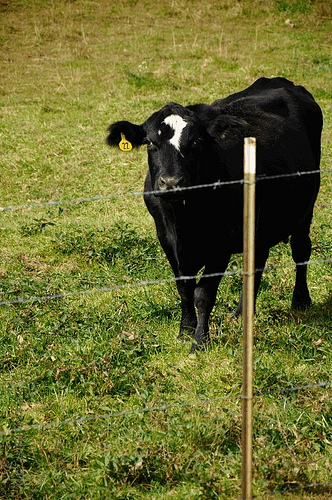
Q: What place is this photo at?
A: It is at the field.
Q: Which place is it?
A: It is a field.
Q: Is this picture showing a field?
A: Yes, it is showing a field.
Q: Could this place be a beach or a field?
A: It is a field.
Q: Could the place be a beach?
A: No, it is a field.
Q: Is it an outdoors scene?
A: Yes, it is outdoors.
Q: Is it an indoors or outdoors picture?
A: It is outdoors.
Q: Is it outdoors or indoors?
A: It is outdoors.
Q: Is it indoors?
A: No, it is outdoors.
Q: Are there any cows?
A: Yes, there is a cow.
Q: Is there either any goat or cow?
A: Yes, there is a cow.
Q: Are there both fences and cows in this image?
A: Yes, there are both a cow and a fence.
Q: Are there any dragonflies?
A: No, there are no dragonflies.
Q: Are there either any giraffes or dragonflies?
A: No, there are no dragonflies or giraffes.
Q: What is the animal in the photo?
A: The animal is a cow.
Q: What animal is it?
A: The animal is a cow.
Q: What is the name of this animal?
A: This is a cow.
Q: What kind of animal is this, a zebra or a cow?
A: This is a cow.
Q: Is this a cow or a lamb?
A: This is a cow.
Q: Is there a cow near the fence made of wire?
A: Yes, there is a cow near the fence.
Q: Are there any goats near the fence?
A: No, there is a cow near the fence.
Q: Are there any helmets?
A: No, there are no helmets.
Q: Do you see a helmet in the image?
A: No, there are no helmets.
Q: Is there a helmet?
A: No, there are no helmets.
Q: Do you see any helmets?
A: No, there are no helmets.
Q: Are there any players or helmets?
A: No, there are no helmets or players.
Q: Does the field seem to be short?
A: Yes, the field is short.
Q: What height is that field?
A: The field is short.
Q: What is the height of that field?
A: The field is short.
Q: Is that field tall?
A: No, the field is short.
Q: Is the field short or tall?
A: The field is short.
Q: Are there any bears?
A: No, there are no bears.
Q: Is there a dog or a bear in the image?
A: No, there are no bears or dogs.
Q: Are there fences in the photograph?
A: Yes, there is a fence.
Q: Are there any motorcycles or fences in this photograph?
A: Yes, there is a fence.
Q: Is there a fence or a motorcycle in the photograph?
A: Yes, there is a fence.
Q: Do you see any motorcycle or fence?
A: Yes, there is a fence.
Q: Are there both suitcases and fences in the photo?
A: No, there is a fence but no suitcases.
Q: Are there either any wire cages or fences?
A: Yes, there is a wire fence.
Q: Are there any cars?
A: No, there are no cars.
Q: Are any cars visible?
A: No, there are no cars.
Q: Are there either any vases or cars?
A: No, there are no cars or vases.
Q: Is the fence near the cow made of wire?
A: Yes, the fence is made of wire.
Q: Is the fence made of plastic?
A: No, the fence is made of wire.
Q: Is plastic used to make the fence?
A: No, the fence is made of wire.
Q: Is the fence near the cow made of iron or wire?
A: The fence is made of wire.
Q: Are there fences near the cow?
A: Yes, there is a fence near the cow.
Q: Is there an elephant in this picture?
A: No, there are no elephants.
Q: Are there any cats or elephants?
A: No, there are no elephants or cats.